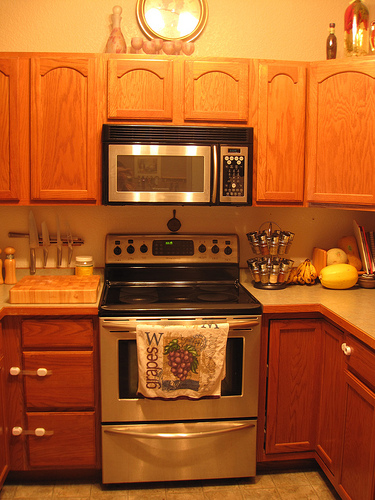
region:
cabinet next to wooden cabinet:
[1, 54, 18, 202]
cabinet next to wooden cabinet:
[28, 56, 95, 199]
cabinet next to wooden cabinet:
[108, 60, 174, 121]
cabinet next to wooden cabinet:
[183, 60, 248, 119]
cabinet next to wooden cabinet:
[256, 64, 301, 202]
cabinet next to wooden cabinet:
[306, 61, 373, 202]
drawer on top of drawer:
[22, 319, 92, 348]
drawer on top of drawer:
[25, 351, 94, 407]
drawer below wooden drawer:
[25, 411, 90, 463]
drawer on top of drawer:
[342, 335, 373, 383]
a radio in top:
[64, 96, 278, 224]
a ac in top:
[81, 120, 270, 201]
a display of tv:
[91, 314, 266, 416]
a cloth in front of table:
[121, 310, 246, 411]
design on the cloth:
[145, 329, 207, 375]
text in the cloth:
[134, 327, 167, 389]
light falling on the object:
[143, 413, 218, 441]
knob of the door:
[0, 418, 76, 435]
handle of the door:
[1, 354, 71, 395]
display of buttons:
[109, 231, 261, 265]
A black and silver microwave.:
[100, 123, 252, 204]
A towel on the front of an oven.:
[134, 324, 228, 399]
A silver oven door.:
[97, 319, 262, 419]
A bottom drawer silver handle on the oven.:
[104, 421, 257, 438]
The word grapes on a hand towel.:
[144, 345, 161, 390]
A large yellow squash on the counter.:
[318, 262, 358, 289]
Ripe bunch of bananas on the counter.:
[290, 259, 317, 286]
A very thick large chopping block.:
[7, 275, 100, 303]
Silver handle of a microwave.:
[209, 144, 217, 204]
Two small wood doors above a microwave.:
[107, 57, 250, 123]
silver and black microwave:
[104, 123, 251, 206]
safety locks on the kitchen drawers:
[5, 362, 53, 439]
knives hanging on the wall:
[25, 210, 73, 272]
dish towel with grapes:
[128, 323, 227, 399]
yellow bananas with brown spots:
[292, 258, 317, 288]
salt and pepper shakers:
[0, 245, 19, 283]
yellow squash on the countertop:
[319, 262, 360, 295]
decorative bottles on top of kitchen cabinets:
[316, 0, 374, 71]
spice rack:
[247, 220, 295, 288]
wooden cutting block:
[8, 273, 101, 304]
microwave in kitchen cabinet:
[85, 109, 258, 212]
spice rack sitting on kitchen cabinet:
[241, 209, 303, 297]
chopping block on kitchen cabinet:
[6, 265, 108, 317]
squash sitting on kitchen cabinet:
[320, 259, 370, 302]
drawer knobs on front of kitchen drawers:
[4, 354, 58, 388]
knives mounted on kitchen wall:
[8, 212, 84, 274]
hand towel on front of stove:
[124, 308, 253, 418]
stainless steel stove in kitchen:
[92, 215, 286, 488]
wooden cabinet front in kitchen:
[264, 308, 371, 451]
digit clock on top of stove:
[143, 226, 194, 269]